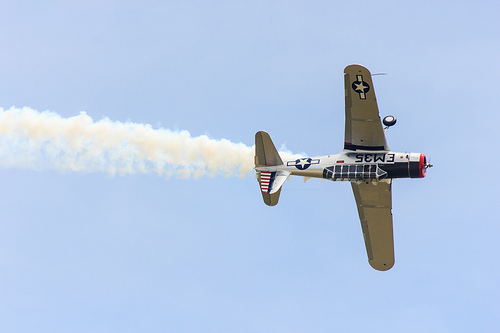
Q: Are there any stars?
A: Yes, there is a star.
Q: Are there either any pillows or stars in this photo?
A: Yes, there is a star.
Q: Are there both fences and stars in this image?
A: No, there is a star but no fences.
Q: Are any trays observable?
A: No, there are no trays.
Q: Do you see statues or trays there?
A: No, there are no trays or statues.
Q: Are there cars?
A: No, there are no cars.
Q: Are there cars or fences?
A: No, there are no cars or fences.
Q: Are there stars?
A: Yes, there is a star.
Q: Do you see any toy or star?
A: Yes, there is a star.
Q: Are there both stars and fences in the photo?
A: No, there is a star but no fences.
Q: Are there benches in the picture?
A: No, there are no benches.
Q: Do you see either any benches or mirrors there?
A: No, there are no benches or mirrors.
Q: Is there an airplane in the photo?
A: Yes, there is an airplane.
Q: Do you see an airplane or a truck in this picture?
A: Yes, there is an airplane.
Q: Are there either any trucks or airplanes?
A: Yes, there is an airplane.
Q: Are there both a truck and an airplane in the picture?
A: No, there is an airplane but no trucks.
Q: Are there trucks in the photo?
A: No, there are no trucks.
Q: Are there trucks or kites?
A: No, there are no trucks or kites.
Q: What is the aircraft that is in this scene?
A: The aircraft is an airplane.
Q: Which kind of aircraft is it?
A: The aircraft is an airplane.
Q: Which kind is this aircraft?
A: This is an airplane.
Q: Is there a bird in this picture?
A: No, there are no birds.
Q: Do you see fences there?
A: No, there are no fences.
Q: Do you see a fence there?
A: No, there are no fences.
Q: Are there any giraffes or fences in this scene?
A: No, there are no fences or giraffes.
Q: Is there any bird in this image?
A: No, there are no birds.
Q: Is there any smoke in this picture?
A: Yes, there is smoke.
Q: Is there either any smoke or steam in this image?
A: Yes, there is smoke.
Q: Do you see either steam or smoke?
A: Yes, there is smoke.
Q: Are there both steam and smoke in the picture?
A: No, there is smoke but no steam.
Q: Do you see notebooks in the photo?
A: No, there are no notebooks.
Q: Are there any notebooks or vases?
A: No, there are no notebooks or vases.